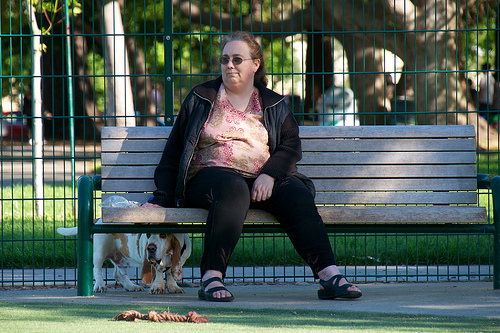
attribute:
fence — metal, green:
[1, 0, 498, 287]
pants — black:
[175, 167, 339, 273]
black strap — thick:
[200, 276, 227, 288]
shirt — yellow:
[198, 79, 270, 171]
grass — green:
[4, 216, 51, 253]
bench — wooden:
[72, 121, 493, 298]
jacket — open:
[140, 68, 318, 204]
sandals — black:
[178, 268, 380, 303]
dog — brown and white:
[57, 220, 192, 294]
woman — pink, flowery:
[152, 25, 360, 300]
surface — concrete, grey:
[394, 283, 425, 295]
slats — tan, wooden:
[99, 123, 480, 137]